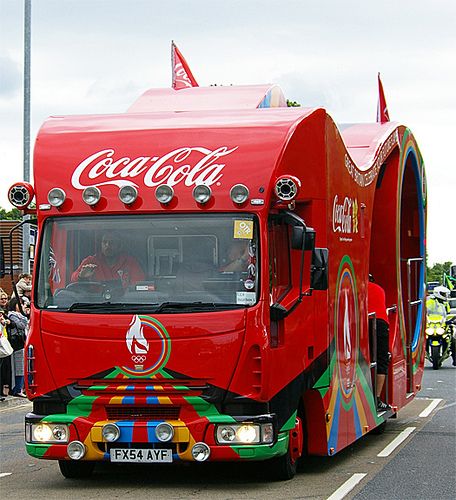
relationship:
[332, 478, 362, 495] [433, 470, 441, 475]
line on road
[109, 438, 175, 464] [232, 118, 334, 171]
license plate of bus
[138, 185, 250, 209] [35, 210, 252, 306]
lights above windshield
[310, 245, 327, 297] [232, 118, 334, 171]
mirror on bus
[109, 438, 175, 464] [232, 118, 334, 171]
license plate on bus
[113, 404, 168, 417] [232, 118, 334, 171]
grill of bus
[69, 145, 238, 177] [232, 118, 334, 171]
coca cola on bus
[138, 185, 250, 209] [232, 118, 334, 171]
lights on bus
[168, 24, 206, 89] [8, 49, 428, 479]
flag on bus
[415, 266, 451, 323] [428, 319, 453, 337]
man on motorcycle